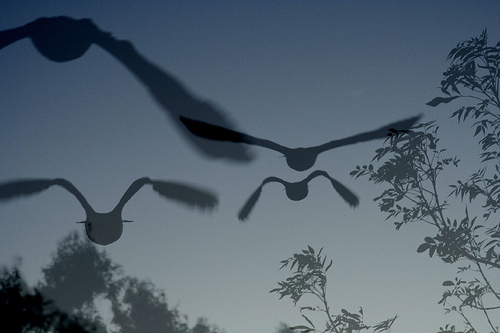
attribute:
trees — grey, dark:
[258, 235, 380, 330]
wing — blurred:
[1, 177, 92, 213]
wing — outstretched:
[318, 110, 421, 158]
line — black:
[122, 217, 135, 224]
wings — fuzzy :
[12, 160, 219, 265]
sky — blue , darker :
[239, 24, 314, 36]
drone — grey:
[176, 112, 429, 173]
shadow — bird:
[0, 12, 260, 166]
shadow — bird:
[178, 107, 426, 172]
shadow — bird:
[3, 173, 221, 247]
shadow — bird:
[233, 168, 359, 218]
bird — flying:
[2, 12, 259, 162]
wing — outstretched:
[178, 115, 286, 157]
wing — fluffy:
[140, 170, 227, 217]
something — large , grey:
[22, 141, 164, 255]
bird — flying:
[0, 175, 220, 245]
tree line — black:
[2, 228, 227, 331]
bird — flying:
[177, 112, 428, 171]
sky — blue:
[0, 1, 499, 331]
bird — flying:
[238, 168, 358, 221]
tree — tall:
[332, 21, 497, 331]